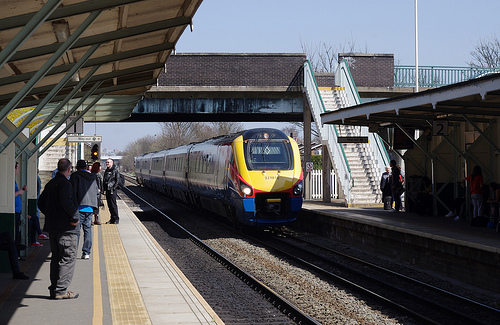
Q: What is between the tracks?
A: Gravel.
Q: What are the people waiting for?
A: The train.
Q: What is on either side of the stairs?
A: A wall.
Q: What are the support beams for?
A: The roof.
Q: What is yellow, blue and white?
A: The train.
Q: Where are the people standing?
A: On the platform.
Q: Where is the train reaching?
A: Platform.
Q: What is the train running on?
A: Tracks.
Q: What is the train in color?
A: Yellow and blue.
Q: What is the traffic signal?
A: Yellow.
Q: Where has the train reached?
A: Near the staircase.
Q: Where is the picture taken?
A: Train station.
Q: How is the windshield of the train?
A: Rectangular.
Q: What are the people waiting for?
A: Train.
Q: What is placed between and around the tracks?
A: Gravel.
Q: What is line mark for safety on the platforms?
A: Yellow line.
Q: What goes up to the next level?
A: Stairs.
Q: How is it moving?
A: By running on traditional tracks.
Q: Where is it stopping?
A: At the train station.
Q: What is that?
A: A train.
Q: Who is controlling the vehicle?
A: The driver.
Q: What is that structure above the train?
A: A walking bridge.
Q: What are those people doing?
A: Waiting for the train to stop.